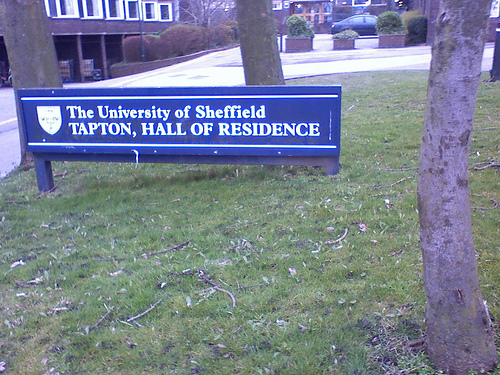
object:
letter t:
[62, 104, 76, 121]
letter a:
[76, 122, 88, 136]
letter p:
[86, 122, 99, 135]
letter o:
[107, 122, 120, 136]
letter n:
[117, 122, 133, 136]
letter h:
[139, 120, 155, 137]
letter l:
[165, 121, 177, 136]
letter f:
[201, 120, 215, 138]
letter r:
[214, 121, 232, 138]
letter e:
[229, 122, 241, 139]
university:
[94, 104, 170, 126]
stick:
[212, 285, 237, 307]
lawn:
[0, 66, 499, 375]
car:
[327, 13, 379, 37]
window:
[44, 0, 61, 18]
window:
[158, 0, 174, 23]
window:
[123, 0, 143, 23]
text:
[62, 104, 322, 138]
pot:
[330, 37, 357, 51]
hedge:
[373, 9, 406, 35]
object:
[90, 67, 104, 82]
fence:
[55, 60, 72, 84]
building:
[0, 0, 180, 83]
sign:
[12, 85, 343, 158]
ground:
[0, 33, 500, 374]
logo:
[34, 105, 64, 136]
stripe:
[25, 142, 338, 151]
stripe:
[19, 94, 338, 101]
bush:
[282, 13, 317, 39]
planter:
[326, 27, 360, 49]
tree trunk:
[415, 0, 496, 375]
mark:
[454, 171, 468, 191]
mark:
[436, 166, 446, 176]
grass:
[0, 69, 500, 375]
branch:
[123, 297, 165, 324]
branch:
[470, 198, 497, 210]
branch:
[213, 285, 237, 309]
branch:
[93, 238, 193, 262]